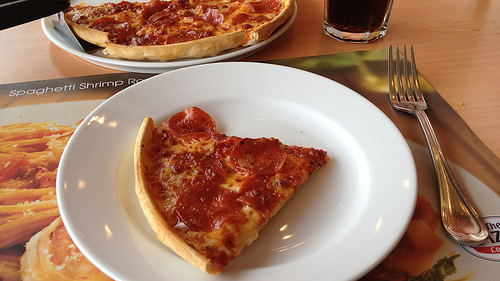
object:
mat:
[0, 47, 500, 281]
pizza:
[133, 107, 327, 274]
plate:
[53, 60, 421, 279]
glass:
[322, 0, 394, 44]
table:
[0, 0, 499, 281]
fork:
[386, 44, 489, 245]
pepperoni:
[169, 107, 216, 137]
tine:
[388, 45, 399, 102]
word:
[9, 83, 76, 97]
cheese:
[154, 136, 210, 153]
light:
[87, 115, 105, 125]